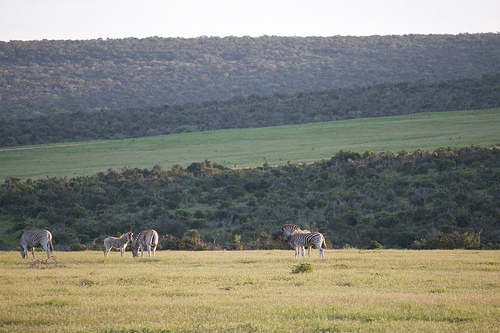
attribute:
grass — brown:
[1, 247, 497, 331]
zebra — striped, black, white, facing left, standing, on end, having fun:
[278, 217, 328, 260]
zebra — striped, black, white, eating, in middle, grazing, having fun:
[128, 228, 160, 259]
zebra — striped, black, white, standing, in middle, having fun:
[98, 230, 135, 257]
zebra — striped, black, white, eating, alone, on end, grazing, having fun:
[17, 224, 57, 263]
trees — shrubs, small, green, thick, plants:
[0, 148, 499, 251]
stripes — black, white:
[290, 229, 327, 260]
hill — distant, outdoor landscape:
[2, 25, 499, 124]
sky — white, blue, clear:
[0, 0, 499, 44]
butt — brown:
[147, 225, 160, 252]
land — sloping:
[1, 106, 499, 187]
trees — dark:
[0, 72, 497, 148]